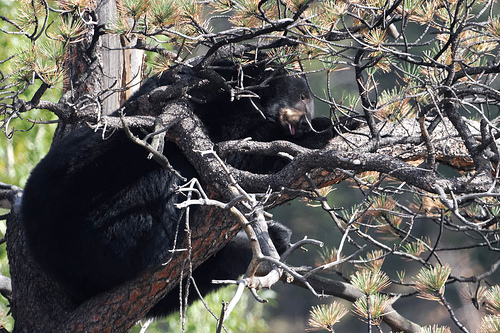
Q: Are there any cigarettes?
A: No, there are no cigarettes.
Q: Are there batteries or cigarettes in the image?
A: No, there are no cigarettes or batteries.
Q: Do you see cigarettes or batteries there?
A: No, there are no cigarettes or batteries.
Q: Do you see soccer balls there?
A: No, there are no soccer balls.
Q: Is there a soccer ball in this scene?
A: No, there are no soccer balls.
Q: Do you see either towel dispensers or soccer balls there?
A: No, there are no soccer balls or towel dispensers.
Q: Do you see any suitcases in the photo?
A: No, there are no suitcases.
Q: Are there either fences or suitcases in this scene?
A: No, there are no suitcases or fences.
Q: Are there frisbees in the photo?
A: No, there are no frisbees.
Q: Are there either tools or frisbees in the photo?
A: No, there are no frisbees or tools.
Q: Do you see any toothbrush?
A: No, there are no toothbrushes.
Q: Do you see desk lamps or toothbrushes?
A: No, there are no toothbrushes or desk lamps.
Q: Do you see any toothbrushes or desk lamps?
A: No, there are no toothbrushes or desk lamps.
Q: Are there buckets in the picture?
A: No, there are no buckets.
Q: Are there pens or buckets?
A: No, there are no buckets or pens.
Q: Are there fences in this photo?
A: No, there are no fences.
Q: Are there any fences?
A: No, there are no fences.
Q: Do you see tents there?
A: No, there are no tents.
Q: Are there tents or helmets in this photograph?
A: No, there are no tents or helmets.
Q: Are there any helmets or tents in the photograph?
A: No, there are no tents or helmets.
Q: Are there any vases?
A: No, there are no vases.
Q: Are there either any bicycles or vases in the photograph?
A: No, there are no vases or bicycles.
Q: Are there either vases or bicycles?
A: No, there are no vases or bicycles.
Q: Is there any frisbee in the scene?
A: No, there are no frisbees.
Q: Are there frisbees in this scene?
A: No, there are no frisbees.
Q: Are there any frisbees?
A: No, there are no frisbees.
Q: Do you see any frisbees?
A: No, there are no frisbees.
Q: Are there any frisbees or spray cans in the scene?
A: No, there are no frisbees or spray cans.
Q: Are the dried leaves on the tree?
A: Yes, the leaves are on the tree.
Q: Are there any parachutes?
A: No, there are no parachutes.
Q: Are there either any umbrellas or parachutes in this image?
A: No, there are no parachutes or umbrellas.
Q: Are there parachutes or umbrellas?
A: No, there are no parachutes or umbrellas.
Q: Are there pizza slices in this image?
A: No, there are no pizza slices.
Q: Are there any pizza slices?
A: No, there are no pizza slices.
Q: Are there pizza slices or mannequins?
A: No, there are no pizza slices or mannequins.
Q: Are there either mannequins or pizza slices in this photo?
A: No, there are no pizza slices or mannequins.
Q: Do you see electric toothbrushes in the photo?
A: No, there are no electric toothbrushes.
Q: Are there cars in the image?
A: No, there are no cars.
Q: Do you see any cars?
A: No, there are no cars.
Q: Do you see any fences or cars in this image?
A: No, there are no cars or fences.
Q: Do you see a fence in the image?
A: No, there are no fences.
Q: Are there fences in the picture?
A: No, there are no fences.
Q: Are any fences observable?
A: No, there are no fences.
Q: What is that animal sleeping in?
A: The animal is sleeping in the tree.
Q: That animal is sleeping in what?
A: The animal is sleeping in the tree.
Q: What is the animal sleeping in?
A: The animal is sleeping in the tree.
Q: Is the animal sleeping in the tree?
A: Yes, the animal is sleeping in the tree.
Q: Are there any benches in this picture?
A: No, there are no benches.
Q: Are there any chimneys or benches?
A: No, there are no benches or chimneys.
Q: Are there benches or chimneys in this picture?
A: No, there are no benches or chimneys.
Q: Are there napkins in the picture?
A: No, there are no napkins.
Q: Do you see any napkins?
A: No, there are no napkins.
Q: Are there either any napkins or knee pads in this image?
A: No, there are no napkins or knee pads.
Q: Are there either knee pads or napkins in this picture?
A: No, there are no napkins or knee pads.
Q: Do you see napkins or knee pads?
A: No, there are no napkins or knee pads.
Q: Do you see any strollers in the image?
A: No, there are no strollers.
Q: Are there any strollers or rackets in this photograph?
A: No, there are no strollers or rackets.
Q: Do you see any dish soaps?
A: No, there are no dish soaps.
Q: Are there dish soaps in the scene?
A: No, there are no dish soaps.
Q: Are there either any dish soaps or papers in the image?
A: No, there are no dish soaps or papers.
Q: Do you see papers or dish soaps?
A: No, there are no dish soaps or papers.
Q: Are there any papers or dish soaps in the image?
A: No, there are no dish soaps or papers.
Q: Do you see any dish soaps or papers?
A: No, there are no dish soaps or papers.